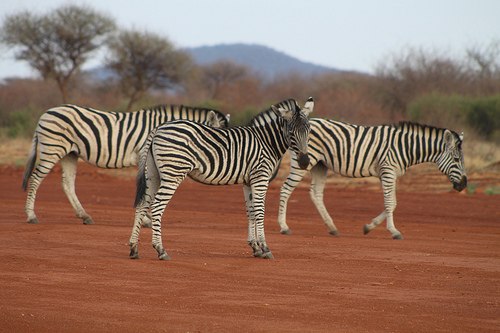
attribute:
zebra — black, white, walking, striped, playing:
[20, 102, 231, 226]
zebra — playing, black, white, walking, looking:
[127, 95, 316, 262]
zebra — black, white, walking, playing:
[276, 115, 467, 241]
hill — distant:
[65, 40, 375, 97]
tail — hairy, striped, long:
[20, 130, 39, 189]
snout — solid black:
[298, 150, 311, 170]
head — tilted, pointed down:
[271, 96, 315, 174]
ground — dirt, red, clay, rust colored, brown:
[1, 162, 499, 332]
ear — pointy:
[270, 104, 291, 123]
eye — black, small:
[453, 156, 460, 164]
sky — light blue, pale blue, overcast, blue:
[0, 0, 499, 83]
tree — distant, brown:
[0, 4, 118, 106]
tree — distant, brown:
[101, 22, 198, 115]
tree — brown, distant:
[184, 54, 268, 117]